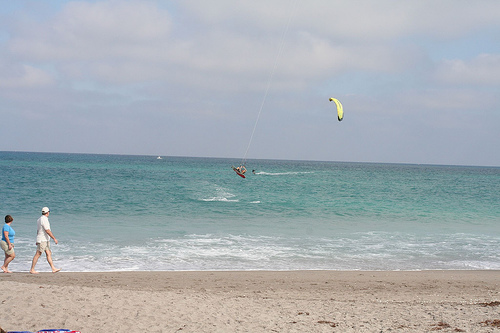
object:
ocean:
[0, 137, 500, 271]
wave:
[189, 181, 261, 206]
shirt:
[35, 214, 60, 246]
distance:
[2, 5, 498, 259]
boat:
[155, 156, 162, 161]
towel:
[3, 324, 73, 332]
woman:
[0, 214, 17, 277]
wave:
[70, 223, 494, 258]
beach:
[1, 270, 499, 333]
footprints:
[314, 317, 338, 326]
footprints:
[481, 298, 498, 308]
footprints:
[483, 317, 498, 326]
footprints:
[433, 320, 453, 329]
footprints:
[450, 327, 465, 331]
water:
[0, 152, 500, 272]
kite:
[324, 93, 348, 124]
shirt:
[3, 221, 15, 244]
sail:
[320, 92, 348, 129]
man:
[246, 160, 265, 178]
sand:
[0, 265, 500, 333]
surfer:
[225, 156, 255, 185]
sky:
[0, 0, 492, 118]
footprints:
[208, 313, 228, 326]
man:
[24, 204, 66, 279]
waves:
[368, 240, 394, 255]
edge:
[0, 265, 498, 276]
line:
[136, 259, 478, 309]